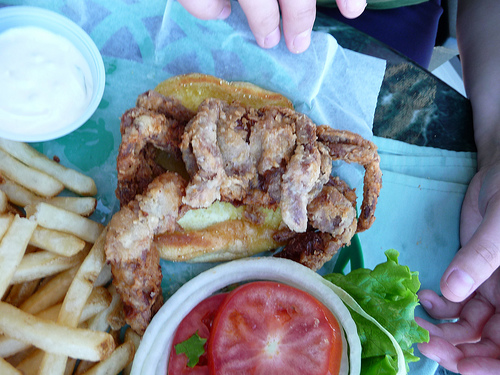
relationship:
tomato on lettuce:
[218, 281, 339, 373] [333, 270, 428, 341]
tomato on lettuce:
[176, 294, 213, 372] [333, 270, 428, 341]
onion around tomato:
[125, 253, 369, 375] [176, 294, 213, 372]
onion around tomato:
[125, 253, 369, 375] [218, 281, 339, 373]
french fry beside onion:
[41, 221, 110, 375] [125, 253, 369, 375]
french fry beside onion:
[28, 199, 107, 245] [125, 253, 369, 375]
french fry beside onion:
[23, 224, 90, 258] [125, 253, 369, 375]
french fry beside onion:
[1, 177, 103, 219] [125, 253, 369, 375]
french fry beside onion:
[1, 297, 116, 365] [125, 253, 369, 375]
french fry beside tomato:
[1, 297, 116, 365] [176, 294, 213, 372]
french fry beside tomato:
[41, 221, 110, 375] [176, 294, 213, 372]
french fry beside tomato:
[23, 224, 90, 258] [176, 294, 213, 372]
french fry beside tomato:
[28, 199, 107, 245] [176, 294, 213, 372]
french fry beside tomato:
[1, 177, 103, 219] [176, 294, 213, 372]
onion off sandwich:
[125, 253, 369, 375] [110, 70, 318, 267]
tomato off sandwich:
[176, 294, 213, 372] [110, 70, 318, 267]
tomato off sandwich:
[218, 281, 339, 373] [110, 70, 318, 267]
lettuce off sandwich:
[333, 270, 428, 341] [110, 70, 318, 267]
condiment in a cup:
[0, 26, 96, 134] [1, 4, 112, 149]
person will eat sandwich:
[172, 0, 498, 373] [110, 70, 318, 267]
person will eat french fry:
[172, 0, 498, 373] [1, 297, 116, 365]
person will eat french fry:
[172, 0, 498, 373] [41, 221, 110, 375]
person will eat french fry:
[172, 0, 498, 373] [23, 224, 90, 258]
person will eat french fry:
[172, 0, 498, 373] [28, 199, 107, 245]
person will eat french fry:
[172, 0, 498, 373] [1, 177, 103, 219]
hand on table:
[173, 0, 371, 56] [3, 3, 486, 373]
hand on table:
[410, 170, 498, 374] [3, 3, 486, 373]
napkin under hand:
[308, 133, 480, 375] [410, 170, 498, 374]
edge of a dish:
[341, 224, 372, 279] [7, 44, 379, 322]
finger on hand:
[413, 288, 462, 320] [410, 170, 498, 374]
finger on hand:
[404, 302, 489, 344] [410, 170, 498, 374]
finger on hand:
[403, 315, 496, 369] [410, 170, 498, 374]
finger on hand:
[441, 350, 499, 374] [410, 170, 498, 374]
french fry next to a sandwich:
[1, 177, 103, 219] [110, 70, 318, 267]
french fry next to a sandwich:
[28, 199, 107, 245] [110, 70, 318, 267]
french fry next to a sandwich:
[23, 224, 90, 258] [110, 70, 318, 267]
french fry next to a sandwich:
[41, 221, 110, 375] [110, 70, 318, 267]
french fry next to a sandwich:
[1, 297, 116, 365] [110, 70, 318, 267]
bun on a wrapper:
[124, 69, 308, 269] [3, 1, 390, 298]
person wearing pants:
[172, 0, 498, 373] [314, 3, 442, 84]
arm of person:
[450, 1, 499, 176] [172, 0, 498, 373]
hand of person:
[173, 0, 371, 56] [172, 0, 498, 373]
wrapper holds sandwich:
[3, 1, 390, 298] [110, 70, 318, 267]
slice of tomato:
[210, 283, 343, 375] [218, 281, 339, 373]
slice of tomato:
[171, 291, 212, 368] [176, 294, 213, 372]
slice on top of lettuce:
[210, 283, 343, 375] [333, 270, 428, 341]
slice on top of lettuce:
[171, 291, 212, 368] [333, 270, 428, 341]